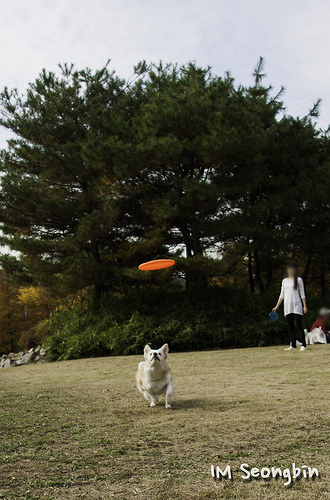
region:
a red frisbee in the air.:
[126, 252, 186, 277]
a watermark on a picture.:
[195, 450, 327, 486]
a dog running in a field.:
[124, 335, 185, 414]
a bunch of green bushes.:
[30, 303, 240, 358]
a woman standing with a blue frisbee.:
[268, 263, 317, 357]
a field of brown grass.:
[3, 341, 328, 498]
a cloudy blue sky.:
[0, 0, 327, 289]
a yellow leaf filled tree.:
[13, 284, 57, 323]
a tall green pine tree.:
[129, 52, 230, 292]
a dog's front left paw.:
[162, 399, 175, 414]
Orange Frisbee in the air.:
[135, 257, 177, 268]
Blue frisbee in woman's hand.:
[261, 309, 277, 319]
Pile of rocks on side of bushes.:
[0, 344, 47, 368]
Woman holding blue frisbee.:
[270, 256, 308, 350]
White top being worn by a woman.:
[276, 269, 302, 314]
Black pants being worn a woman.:
[285, 313, 306, 347]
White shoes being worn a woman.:
[284, 344, 308, 352]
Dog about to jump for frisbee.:
[132, 335, 180, 414]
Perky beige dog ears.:
[143, 342, 168, 352]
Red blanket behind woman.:
[307, 316, 326, 334]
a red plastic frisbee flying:
[138, 256, 174, 272]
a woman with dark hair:
[271, 264, 309, 351]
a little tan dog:
[132, 339, 176, 407]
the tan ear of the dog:
[159, 343, 168, 352]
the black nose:
[151, 350, 156, 355]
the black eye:
[148, 351, 153, 357]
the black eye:
[157, 351, 160, 355]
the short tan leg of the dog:
[146, 388, 159, 407]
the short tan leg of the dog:
[165, 383, 175, 407]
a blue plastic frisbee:
[268, 309, 279, 321]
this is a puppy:
[133, 344, 177, 404]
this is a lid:
[132, 255, 178, 275]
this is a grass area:
[36, 397, 86, 496]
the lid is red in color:
[143, 260, 155, 263]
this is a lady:
[275, 259, 300, 344]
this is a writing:
[204, 461, 316, 486]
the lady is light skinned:
[274, 297, 278, 299]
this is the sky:
[136, 11, 224, 36]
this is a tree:
[129, 71, 237, 196]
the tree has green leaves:
[118, 94, 144, 132]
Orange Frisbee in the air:
[135, 252, 175, 270]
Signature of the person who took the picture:
[204, 462, 317, 487]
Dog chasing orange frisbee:
[134, 339, 174, 411]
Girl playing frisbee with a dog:
[264, 264, 308, 354]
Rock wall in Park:
[0, 332, 48, 377]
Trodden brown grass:
[17, 372, 72, 418]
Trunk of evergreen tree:
[183, 249, 207, 285]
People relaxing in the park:
[309, 304, 326, 341]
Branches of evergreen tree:
[0, 172, 82, 210]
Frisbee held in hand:
[265, 305, 279, 322]